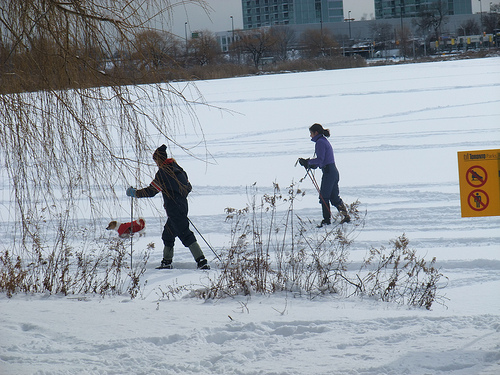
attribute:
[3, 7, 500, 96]
trees — beautiful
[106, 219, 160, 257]
dog — small, brown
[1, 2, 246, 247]
tree — old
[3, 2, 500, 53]
sky — clear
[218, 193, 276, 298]
plant — part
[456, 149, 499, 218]
board — part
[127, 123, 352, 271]
people — skiing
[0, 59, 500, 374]
snow — skiid, white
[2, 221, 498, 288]
trail — park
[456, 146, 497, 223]
sign — yellow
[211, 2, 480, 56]
buildings — distant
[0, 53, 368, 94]
grass — poking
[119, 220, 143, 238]
outfit — red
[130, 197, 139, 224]
leash — black